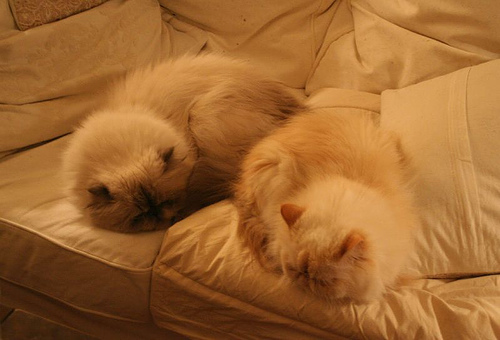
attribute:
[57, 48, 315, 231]
cat — white, sleeping, furry, black, fluffy, here, fat, lying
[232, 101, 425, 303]
cat — white, sleeping, furry, tan, orange, fluffy, here, lying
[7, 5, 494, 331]
couch — white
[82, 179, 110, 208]
ear — cat's, small, short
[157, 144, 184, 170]
ear — cat's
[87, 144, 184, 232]
face — cat's, black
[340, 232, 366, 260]
ear — cat's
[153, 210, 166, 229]
nose — cat's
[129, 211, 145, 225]
eye — cat's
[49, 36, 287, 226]
kitten — sleeping, fuzzy, tan, white, small, resting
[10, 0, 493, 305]
sofa — white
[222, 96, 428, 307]
kitten — sleeping, fuzzy, small, resting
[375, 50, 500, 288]
pillow — white, here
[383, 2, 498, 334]
side — kitten's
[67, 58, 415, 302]
kittens — sleeping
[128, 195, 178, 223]
eyes — closed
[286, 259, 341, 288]
eyes — closed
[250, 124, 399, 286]
fur — light, brown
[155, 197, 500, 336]
cushion — tan, seat, wrinkly, smooth, comfy, beige, couch's, worn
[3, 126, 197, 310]
cushion — comfy